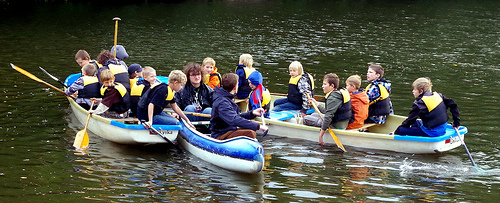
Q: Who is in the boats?
A: Children.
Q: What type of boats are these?
A: Small row boats.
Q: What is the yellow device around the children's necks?
A: Life jackets.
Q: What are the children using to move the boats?
A: Yellow paddles.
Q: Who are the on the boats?
A: Children.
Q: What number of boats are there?
A: 3.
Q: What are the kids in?
A: Canoes.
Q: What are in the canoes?
A: Kids.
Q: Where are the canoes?
A: In the water.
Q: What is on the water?
A: Kids in canoes.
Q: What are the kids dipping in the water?
A: Oars.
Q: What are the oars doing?
A: Being dipped in the water to paddle the canoes.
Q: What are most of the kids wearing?
A: A blue and yellow vest.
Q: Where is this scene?
A: Kids canoeing on the water.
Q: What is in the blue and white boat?
A: A group of boys.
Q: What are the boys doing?
A: Boating together.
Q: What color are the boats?
A: Blue, yellow and white.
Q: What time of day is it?
A: Daytime.